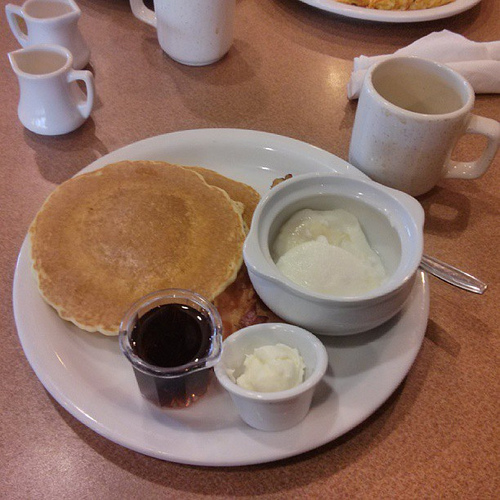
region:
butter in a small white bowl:
[214, 320, 331, 435]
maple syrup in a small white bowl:
[118, 287, 223, 410]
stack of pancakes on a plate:
[40, 155, 269, 349]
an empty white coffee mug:
[349, 61, 496, 191]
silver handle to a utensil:
[411, 241, 488, 298]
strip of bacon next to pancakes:
[219, 164, 296, 374]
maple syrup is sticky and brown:
[126, 295, 218, 406]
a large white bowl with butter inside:
[240, 170, 427, 333]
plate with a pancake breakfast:
[12, 113, 439, 477]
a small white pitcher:
[5, 41, 101, 138]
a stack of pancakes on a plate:
[26, 162, 259, 338]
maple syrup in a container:
[115, 291, 220, 412]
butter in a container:
[216, 323, 326, 433]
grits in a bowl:
[254, 169, 428, 316]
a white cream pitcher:
[7, 44, 95, 141]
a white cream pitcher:
[5, 1, 89, 43]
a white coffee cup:
[347, 52, 497, 190]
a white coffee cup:
[123, 0, 236, 68]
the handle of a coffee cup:
[446, 115, 498, 187]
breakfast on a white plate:
[22, 135, 434, 447]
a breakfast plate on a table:
[3, 84, 469, 494]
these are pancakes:
[39, 130, 262, 367]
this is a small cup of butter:
[218, 310, 355, 444]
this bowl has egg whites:
[251, 160, 441, 329]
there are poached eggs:
[262, 176, 441, 333]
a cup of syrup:
[119, 287, 228, 414]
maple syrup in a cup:
[110, 267, 253, 424]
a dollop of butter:
[216, 319, 323, 427]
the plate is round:
[8, 121, 485, 498]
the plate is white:
[14, 101, 468, 498]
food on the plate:
[41, 150, 234, 307]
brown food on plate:
[58, 203, 170, 283]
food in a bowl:
[276, 213, 386, 293]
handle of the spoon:
[423, 252, 488, 315]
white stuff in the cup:
[242, 336, 307, 392]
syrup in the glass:
[127, 300, 207, 367]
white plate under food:
[21, 345, 96, 435]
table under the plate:
[399, 401, 482, 468]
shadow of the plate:
[79, 458, 151, 493]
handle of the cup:
[62, 56, 109, 116]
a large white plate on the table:
[10, 128, 429, 469]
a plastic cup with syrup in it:
[118, 293, 225, 413]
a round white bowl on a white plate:
[240, 172, 424, 337]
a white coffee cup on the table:
[347, 55, 497, 197]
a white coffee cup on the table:
[132, 0, 237, 65]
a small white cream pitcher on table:
[8, 43, 95, 137]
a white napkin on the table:
[347, 28, 498, 98]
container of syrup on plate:
[110, 284, 226, 411]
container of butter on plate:
[212, 309, 330, 436]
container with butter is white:
[210, 314, 325, 431]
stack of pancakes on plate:
[25, 153, 276, 364]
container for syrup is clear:
[111, 286, 226, 414]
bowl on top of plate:
[234, 166, 421, 338]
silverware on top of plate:
[407, 244, 482, 312]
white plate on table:
[18, 121, 439, 468]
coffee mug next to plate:
[337, 49, 498, 211]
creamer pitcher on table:
[5, 41, 101, 131]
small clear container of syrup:
[118, 288, 225, 403]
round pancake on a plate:
[31, 158, 246, 334]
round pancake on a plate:
[183, 165, 262, 333]